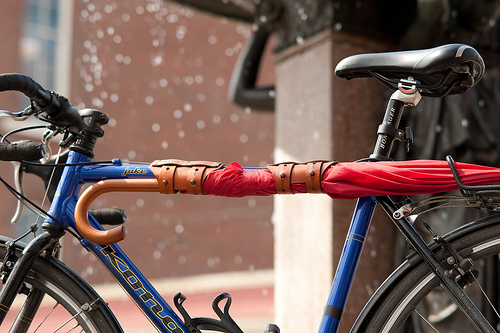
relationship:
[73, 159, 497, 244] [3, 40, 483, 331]
umbrella on bike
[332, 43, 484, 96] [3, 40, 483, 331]
seat on bike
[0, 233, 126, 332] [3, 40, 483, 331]
tire on bike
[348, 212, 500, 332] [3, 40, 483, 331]
tire on bike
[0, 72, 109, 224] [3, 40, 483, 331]
handle bars on bike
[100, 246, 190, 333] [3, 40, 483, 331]
black lettering on bike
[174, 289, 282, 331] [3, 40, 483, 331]
cupholder on bike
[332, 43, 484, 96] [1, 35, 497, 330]
seat on bicycle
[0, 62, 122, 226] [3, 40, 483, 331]
handle bars on bike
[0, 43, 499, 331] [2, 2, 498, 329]
bicycle sitting outside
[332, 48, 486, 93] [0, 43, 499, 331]
seat of bicycle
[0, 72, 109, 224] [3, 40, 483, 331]
handle bars of bike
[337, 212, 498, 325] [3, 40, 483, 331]
tire of bike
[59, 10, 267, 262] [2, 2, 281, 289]
specks on wall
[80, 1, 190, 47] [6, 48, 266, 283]
specks on wall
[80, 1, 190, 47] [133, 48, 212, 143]
specks on wall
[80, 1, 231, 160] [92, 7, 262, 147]
specks on wall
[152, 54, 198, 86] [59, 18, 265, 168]
specks on wall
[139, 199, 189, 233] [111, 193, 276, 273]
specks on wall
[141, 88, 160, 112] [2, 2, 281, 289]
speck on wall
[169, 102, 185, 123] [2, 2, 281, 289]
speck on wall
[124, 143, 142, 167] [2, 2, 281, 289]
speck on wall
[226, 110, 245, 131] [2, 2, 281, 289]
speck on wall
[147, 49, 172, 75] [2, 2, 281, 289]
speck on wall